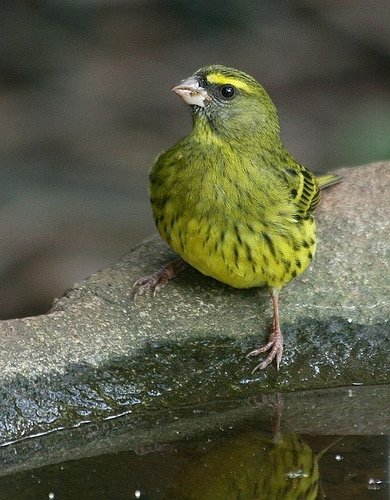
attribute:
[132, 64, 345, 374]
bird — little, perched, feathery, present, green, refecleting, black, standing, reflecting, looking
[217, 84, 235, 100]
eye — black, striped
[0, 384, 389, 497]
water — reflecting, small, dark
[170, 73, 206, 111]
beak — present, white, small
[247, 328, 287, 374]
foot — stretched, pink, small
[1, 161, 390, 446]
stone — grey, gray, wet